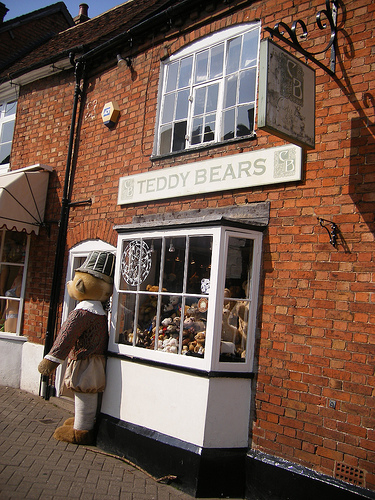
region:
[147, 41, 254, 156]
a glass window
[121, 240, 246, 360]
a window filled with stuffed animals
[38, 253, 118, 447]
a large stuffed Teddy Bear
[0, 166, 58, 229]
awning above a window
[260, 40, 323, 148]
sign hangs from side of building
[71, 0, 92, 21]
a chimney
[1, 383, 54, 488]
sidewalk paved with brick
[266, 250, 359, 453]
red brick wall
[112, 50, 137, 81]
a lamp mounted in a wall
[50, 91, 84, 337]
metal pipes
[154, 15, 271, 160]
large window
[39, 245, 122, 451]
stuffed large bear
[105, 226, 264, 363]
teddy bears on display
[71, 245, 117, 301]
hat on top of stuffed bear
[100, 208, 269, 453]
large bay window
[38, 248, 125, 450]
large teddy bear standing by door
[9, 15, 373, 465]
building with red brick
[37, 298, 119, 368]
stuffed bear wearing a sweater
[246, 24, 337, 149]
store sign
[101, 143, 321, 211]
store sign on wall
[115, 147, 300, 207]
The white sign that reads Teddy Bears.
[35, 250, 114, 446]
The bear standing outside of the shop.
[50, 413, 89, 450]
The bear's brown feet standing outside of the shop.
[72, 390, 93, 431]
The white leg of the bear standing outside of the shop.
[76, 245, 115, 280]
The black and white stripe hat of the bear standing outside of the shop.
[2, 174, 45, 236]
The black and white canopy next to the shop.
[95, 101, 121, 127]
The ADT sign mounted on the building.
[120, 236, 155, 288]
The circle design on the shop's window.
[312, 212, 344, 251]
The small wrought iron fixture mounted on the brick wall.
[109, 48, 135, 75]
The spotlight at the top of the building.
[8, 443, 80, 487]
Brick ground surface outside the shop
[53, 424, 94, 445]
Furry left foot of the bear outside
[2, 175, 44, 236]
Awning above the shop window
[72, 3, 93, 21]
Chimney on the roof of the building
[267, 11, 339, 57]
Wrought iron scrollwork supporting the hanging sign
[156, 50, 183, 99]
Top window pane in the left corner of the second story window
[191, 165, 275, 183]
The word BEARS on the sign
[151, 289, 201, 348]
Cluster of animals in the shop window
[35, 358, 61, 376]
Left paw of the bear standing outside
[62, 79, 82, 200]
Pipe running down the side of the building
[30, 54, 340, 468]
a teddy bear shop in a brick building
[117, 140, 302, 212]
the Teddy Bears sign to the shop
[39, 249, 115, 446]
a lifesize teddy bear on display outside the shop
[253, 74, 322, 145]
an old sign in need of repair hanging above the shop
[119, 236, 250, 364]
a shop window with tons of stuffed animals in it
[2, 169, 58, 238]
a white awning to the business next door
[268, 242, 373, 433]
the red brick wall of the building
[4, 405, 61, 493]
a grey brick sidewalk outside the shop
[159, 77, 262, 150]
a very old window in the second floor of the building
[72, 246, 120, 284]
a grey bucket hat on the display teddy bear